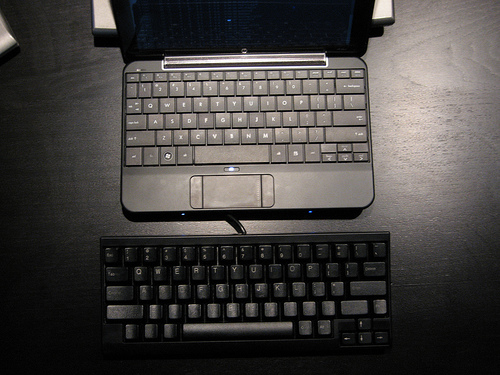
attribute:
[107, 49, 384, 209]
laptop — black, silver, small, open, gray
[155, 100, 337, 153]
keyboard — plugged in, black, white, sitting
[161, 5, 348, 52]
screen — dark